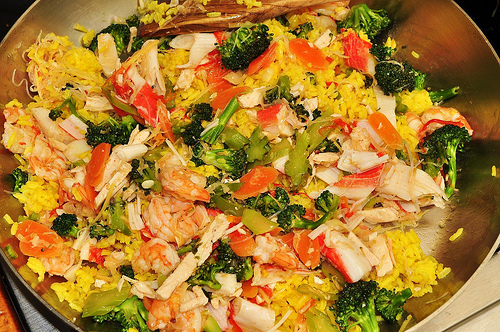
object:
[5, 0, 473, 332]
meal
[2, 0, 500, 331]
bowl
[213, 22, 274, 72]
broccoli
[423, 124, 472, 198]
broccoli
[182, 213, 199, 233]
shrimp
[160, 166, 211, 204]
shrimp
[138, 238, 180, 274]
shrimp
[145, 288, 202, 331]
shrimp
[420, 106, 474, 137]
shrimp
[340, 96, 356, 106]
rice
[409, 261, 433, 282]
rice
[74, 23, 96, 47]
rice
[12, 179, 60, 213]
rice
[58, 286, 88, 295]
rice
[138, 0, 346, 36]
spoon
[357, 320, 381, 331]
stem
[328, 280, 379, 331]
broccoli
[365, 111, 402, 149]
carrot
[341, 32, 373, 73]
crab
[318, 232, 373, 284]
crab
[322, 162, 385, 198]
crab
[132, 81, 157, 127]
crab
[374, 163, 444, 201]
crab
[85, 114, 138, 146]
broccoli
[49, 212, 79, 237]
broccoli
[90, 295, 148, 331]
broccoli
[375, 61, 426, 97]
broccoli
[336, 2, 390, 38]
broccoli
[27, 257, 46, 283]
rice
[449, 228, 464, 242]
rice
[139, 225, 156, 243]
red pepper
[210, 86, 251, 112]
red pepper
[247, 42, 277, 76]
red pepper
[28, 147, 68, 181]
shrimp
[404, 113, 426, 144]
shrimp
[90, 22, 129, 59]
broccoli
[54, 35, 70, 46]
grain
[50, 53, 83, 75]
rice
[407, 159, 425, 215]
noodle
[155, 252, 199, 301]
chunk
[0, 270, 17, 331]
table